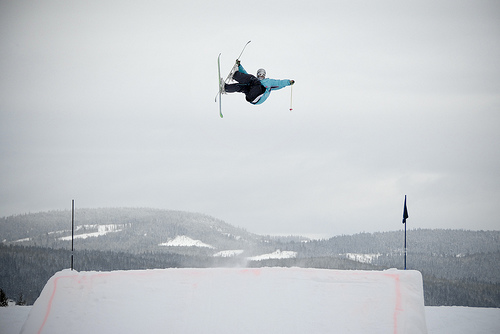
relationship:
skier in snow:
[211, 38, 302, 121] [2, 276, 497, 331]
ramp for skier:
[28, 270, 422, 331] [211, 38, 302, 121]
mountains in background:
[1, 210, 497, 306] [8, 1, 495, 270]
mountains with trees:
[1, 210, 497, 306] [5, 212, 497, 301]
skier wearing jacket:
[211, 38, 302, 121] [255, 76, 298, 107]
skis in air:
[212, 34, 253, 126] [13, 3, 492, 203]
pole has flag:
[402, 195, 413, 272] [401, 193, 412, 225]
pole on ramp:
[70, 196, 79, 270] [28, 270, 422, 331]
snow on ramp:
[2, 276, 497, 331] [28, 270, 422, 331]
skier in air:
[211, 38, 302, 121] [13, 3, 492, 203]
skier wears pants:
[211, 38, 302, 121] [223, 74, 264, 102]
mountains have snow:
[1, 210, 497, 306] [2, 276, 497, 331]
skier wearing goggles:
[211, 38, 302, 121] [258, 72, 266, 76]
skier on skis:
[211, 38, 302, 121] [212, 34, 253, 126]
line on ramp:
[389, 275, 408, 329] [28, 270, 422, 331]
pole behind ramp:
[70, 196, 79, 270] [28, 270, 422, 331]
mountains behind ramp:
[1, 210, 497, 306] [28, 270, 422, 331]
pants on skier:
[223, 74, 264, 102] [211, 38, 302, 121]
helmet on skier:
[255, 69, 268, 77] [211, 38, 302, 121]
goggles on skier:
[258, 72, 266, 76] [211, 38, 302, 121]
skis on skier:
[212, 34, 253, 126] [211, 38, 302, 121]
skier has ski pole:
[211, 38, 302, 121] [288, 84, 295, 117]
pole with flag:
[70, 196, 79, 270] [401, 193, 412, 225]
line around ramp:
[389, 275, 408, 329] [28, 270, 422, 331]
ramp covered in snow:
[28, 270, 422, 331] [2, 276, 497, 331]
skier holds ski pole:
[211, 38, 302, 121] [288, 84, 295, 117]